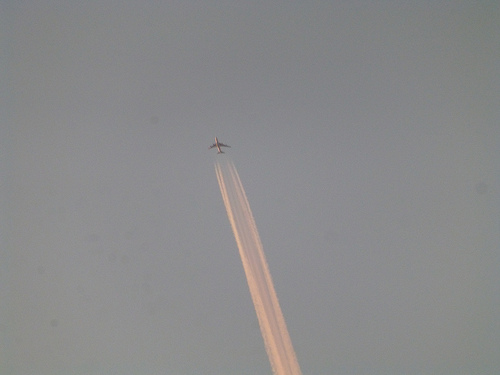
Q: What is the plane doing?
A: Flying.